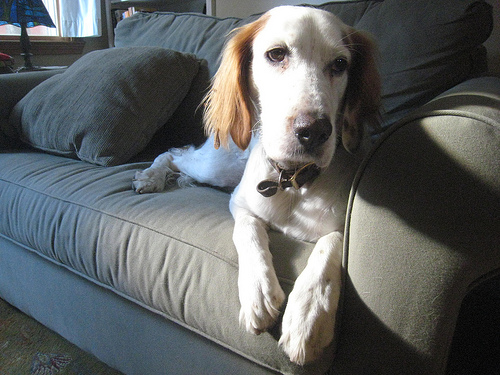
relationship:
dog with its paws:
[128, 4, 387, 365] [230, 225, 342, 367]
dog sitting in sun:
[128, 4, 387, 365] [145, 179, 293, 363]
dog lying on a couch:
[128, 4, 387, 365] [1, 0, 484, 370]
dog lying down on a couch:
[128, 4, 387, 365] [1, 0, 484, 370]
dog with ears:
[128, 4, 387, 365] [197, 14, 387, 151]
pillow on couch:
[4, 43, 202, 167] [1, 0, 484, 370]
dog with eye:
[128, 4, 387, 365] [265, 48, 286, 63]